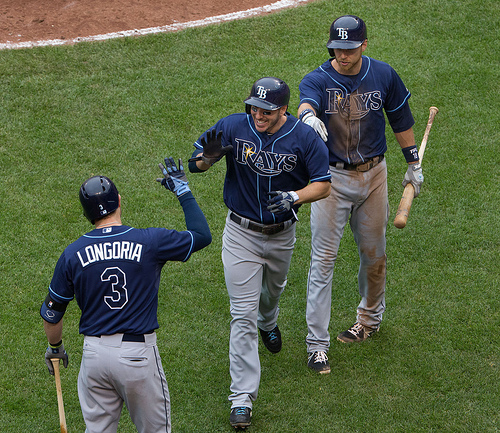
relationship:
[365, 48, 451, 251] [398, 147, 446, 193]
bat in hand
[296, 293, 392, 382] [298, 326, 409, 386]
shoes have laces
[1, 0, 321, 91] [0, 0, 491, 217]
border on field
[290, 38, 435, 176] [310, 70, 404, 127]
jersey printed longoria 3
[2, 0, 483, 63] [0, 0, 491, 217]
grass on field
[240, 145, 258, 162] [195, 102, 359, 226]
star on shirt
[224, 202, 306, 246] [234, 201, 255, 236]
belt in holder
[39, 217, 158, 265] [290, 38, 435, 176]
name on jersey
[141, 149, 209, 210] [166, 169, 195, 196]
gloves have two tones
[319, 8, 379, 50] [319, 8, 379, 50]
helmet on helmet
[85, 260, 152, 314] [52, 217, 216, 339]
number on jersey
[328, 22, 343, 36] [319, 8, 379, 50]
t on helmet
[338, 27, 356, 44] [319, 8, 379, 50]
b on helmet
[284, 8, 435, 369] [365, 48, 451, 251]
player holding bat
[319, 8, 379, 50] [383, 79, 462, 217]
helmet for batting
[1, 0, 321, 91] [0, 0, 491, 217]
line on field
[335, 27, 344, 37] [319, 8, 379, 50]
t on helmet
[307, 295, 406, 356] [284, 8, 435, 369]
cleat of player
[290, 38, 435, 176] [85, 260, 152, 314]
jersey with number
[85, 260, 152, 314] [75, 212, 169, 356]
number on back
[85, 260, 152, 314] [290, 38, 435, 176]
number on jersey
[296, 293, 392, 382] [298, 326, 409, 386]
cleats have laces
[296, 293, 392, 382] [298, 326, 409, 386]
shoes with laces